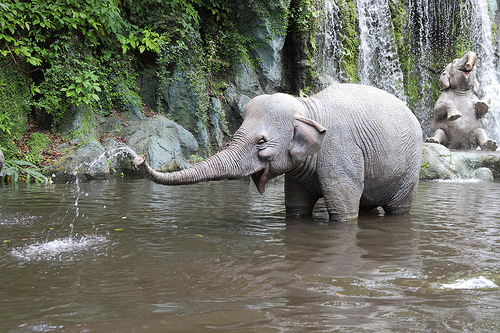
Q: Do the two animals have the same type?
A: Yes, all the animals are elephants.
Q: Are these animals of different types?
A: No, all the animals are elephants.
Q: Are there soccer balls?
A: No, there are no soccer balls.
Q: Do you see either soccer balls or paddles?
A: No, there are no soccer balls or paddles.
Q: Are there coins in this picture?
A: No, there are no coins.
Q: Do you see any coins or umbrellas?
A: No, there are no coins or umbrellas.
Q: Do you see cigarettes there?
A: No, there are no cigarettes.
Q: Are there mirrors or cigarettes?
A: No, there are no cigarettes or mirrors.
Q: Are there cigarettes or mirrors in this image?
A: No, there are no cigarettes or mirrors.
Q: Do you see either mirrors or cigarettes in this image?
A: No, there are no cigarettes or mirrors.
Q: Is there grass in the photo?
A: Yes, there is grass.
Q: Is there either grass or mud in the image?
A: Yes, there is grass.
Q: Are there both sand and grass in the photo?
A: No, there is grass but no sand.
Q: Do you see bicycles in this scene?
A: No, there are no bicycles.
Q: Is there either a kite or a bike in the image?
A: No, there are no bikes or kites.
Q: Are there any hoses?
A: No, there are no hoses.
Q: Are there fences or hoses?
A: No, there are no hoses or fences.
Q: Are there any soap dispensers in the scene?
A: No, there are no soap dispensers.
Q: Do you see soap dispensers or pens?
A: No, there are no soap dispensers or pens.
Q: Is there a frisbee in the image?
A: No, there are no frisbees.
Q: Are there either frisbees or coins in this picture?
A: No, there are no frisbees or coins.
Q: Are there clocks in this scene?
A: No, there are no clocks.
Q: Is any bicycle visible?
A: No, there are no bicycles.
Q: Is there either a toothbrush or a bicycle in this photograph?
A: No, there are no bicycles or toothbrushes.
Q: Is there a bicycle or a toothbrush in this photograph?
A: No, there are no bicycles or toothbrushes.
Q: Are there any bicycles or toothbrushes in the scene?
A: No, there are no bicycles or toothbrushes.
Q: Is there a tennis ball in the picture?
A: No, there are no tennis balls.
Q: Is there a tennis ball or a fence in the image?
A: No, there are no tennis balls or fences.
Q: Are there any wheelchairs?
A: No, there are no wheelchairs.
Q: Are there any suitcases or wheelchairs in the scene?
A: No, there are no wheelchairs or suitcases.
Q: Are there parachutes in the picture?
A: No, there are no parachutes.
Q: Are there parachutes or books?
A: No, there are no parachutes or books.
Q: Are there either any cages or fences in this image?
A: No, there are no fences or cages.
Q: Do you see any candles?
A: No, there are no candles.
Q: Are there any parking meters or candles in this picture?
A: No, there are no candles or parking meters.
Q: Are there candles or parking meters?
A: No, there are no candles or parking meters.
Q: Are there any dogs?
A: No, there are no dogs.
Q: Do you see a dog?
A: No, there are no dogs.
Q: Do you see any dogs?
A: No, there are no dogs.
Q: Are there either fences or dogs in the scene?
A: No, there are no dogs or fences.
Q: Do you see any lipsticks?
A: No, there are no lipsticks.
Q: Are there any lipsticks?
A: No, there are no lipsticks.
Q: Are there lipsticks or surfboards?
A: No, there are no lipsticks or surfboards.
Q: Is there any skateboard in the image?
A: No, there are no skateboards.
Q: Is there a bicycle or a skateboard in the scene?
A: No, there are no skateboards or bicycles.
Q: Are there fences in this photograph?
A: No, there are no fences.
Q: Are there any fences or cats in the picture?
A: No, there are no fences or cats.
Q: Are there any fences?
A: No, there are no fences.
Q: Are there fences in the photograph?
A: No, there are no fences.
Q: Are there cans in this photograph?
A: No, there are no cans.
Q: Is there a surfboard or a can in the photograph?
A: No, there are no cans or surfboards.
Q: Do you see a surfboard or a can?
A: No, there are no cans or surfboards.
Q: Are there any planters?
A: No, there are no planters.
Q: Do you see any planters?
A: No, there are no planters.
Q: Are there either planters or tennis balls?
A: No, there are no planters or tennis balls.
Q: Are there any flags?
A: No, there are no flags.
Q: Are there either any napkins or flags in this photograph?
A: No, there are no flags or napkins.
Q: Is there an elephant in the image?
A: Yes, there is an elephant.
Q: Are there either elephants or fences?
A: Yes, there is an elephant.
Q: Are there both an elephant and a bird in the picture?
A: No, there is an elephant but no birds.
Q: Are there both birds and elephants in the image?
A: No, there is an elephant but no birds.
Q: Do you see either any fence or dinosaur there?
A: No, there are no fences or dinosaurs.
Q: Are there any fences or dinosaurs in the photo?
A: No, there are no fences or dinosaurs.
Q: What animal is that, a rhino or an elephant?
A: That is an elephant.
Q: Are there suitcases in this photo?
A: No, there are no suitcases.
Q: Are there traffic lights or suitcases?
A: No, there are no suitcases or traffic lights.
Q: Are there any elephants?
A: Yes, there is an elephant.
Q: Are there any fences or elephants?
A: Yes, there is an elephant.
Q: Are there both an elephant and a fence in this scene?
A: No, there is an elephant but no fences.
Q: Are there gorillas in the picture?
A: No, there are no gorillas.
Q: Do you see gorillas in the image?
A: No, there are no gorillas.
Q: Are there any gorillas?
A: No, there are no gorillas.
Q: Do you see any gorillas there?
A: No, there are no gorillas.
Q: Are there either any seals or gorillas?
A: No, there are no gorillas or seals.